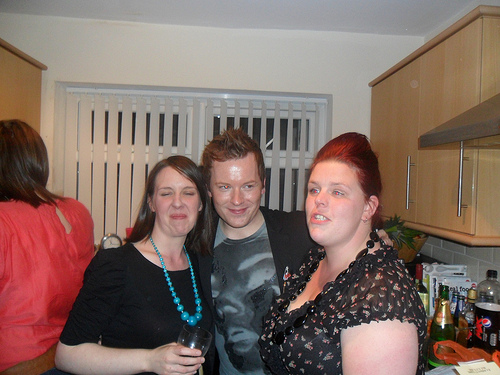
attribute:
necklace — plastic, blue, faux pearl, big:
[160, 254, 206, 330]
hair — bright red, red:
[349, 135, 386, 193]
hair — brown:
[6, 131, 46, 188]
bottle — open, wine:
[436, 285, 454, 352]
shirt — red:
[4, 216, 81, 358]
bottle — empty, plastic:
[474, 273, 500, 347]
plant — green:
[388, 217, 414, 258]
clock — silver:
[96, 233, 123, 253]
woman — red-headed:
[288, 131, 414, 374]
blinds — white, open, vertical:
[81, 116, 315, 186]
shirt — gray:
[214, 246, 290, 374]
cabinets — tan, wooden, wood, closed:
[368, 64, 489, 229]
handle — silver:
[399, 151, 429, 225]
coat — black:
[258, 212, 310, 283]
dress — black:
[101, 261, 208, 369]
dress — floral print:
[285, 272, 427, 374]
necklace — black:
[278, 272, 343, 336]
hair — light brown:
[207, 133, 257, 167]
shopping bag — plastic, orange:
[424, 344, 499, 366]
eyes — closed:
[154, 185, 206, 201]